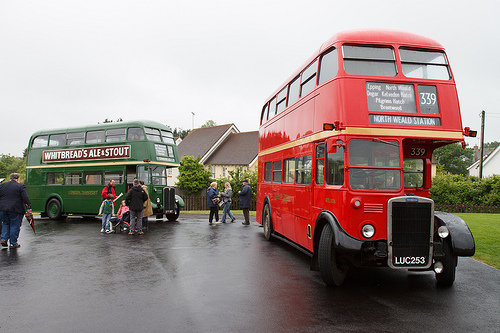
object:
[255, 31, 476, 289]
bus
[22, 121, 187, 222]
bus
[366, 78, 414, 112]
sign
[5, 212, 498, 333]
pavement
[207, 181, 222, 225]
woman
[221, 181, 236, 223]
woman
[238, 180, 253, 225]
man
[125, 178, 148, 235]
man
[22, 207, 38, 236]
umbrella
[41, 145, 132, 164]
sign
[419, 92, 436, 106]
339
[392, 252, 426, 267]
license plate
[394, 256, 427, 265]
luc253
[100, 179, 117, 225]
man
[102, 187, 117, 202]
jacket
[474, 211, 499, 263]
lawn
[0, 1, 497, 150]
sky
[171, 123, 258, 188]
house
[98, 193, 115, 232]
child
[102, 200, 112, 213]
vest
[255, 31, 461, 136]
upper deck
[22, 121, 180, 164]
upper deck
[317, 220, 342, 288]
wheel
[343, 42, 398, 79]
window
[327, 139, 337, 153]
mirror